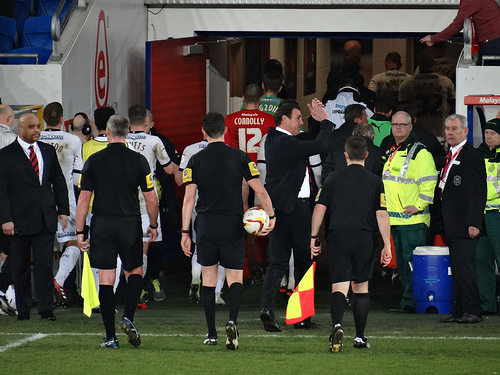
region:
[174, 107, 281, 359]
A man holding a soccer ball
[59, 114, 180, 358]
A referee holding a yellow flag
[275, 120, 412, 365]
A referee holding a checkered flag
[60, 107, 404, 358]
Three referees walking into a tunnel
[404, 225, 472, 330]
A blue water cooler on a field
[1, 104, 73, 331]
A man in a blue suit looking at something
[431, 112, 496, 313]
A man in a suit looking at something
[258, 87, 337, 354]
A man clapping his hands in the air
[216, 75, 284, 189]
A player in a red jersey walking into a tunnel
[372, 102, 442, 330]
A man in a yellow jacket looking at something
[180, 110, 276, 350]
Man wearing uniform holding red and white ball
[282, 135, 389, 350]
Man in uniform holding flag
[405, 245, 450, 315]
Blue and white water cooler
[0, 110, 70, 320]
Man in black tuxedo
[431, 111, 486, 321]
Man standing and watching players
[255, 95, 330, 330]
Man walking and making motion with hands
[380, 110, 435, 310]
Man wearing yellow and gray shirt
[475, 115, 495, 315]
Man wearing a black knit toboggan hat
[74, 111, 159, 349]
Man wearing uniform holding yellow towel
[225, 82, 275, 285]
Man wearing a red jersey with white letters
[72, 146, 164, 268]
man wearing black and yellow soccer uniform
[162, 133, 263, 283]
man wearing black and yellow soccer uniform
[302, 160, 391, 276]
man wearing black and yellow soccer uniform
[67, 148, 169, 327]
young man wearing black and yellow soccer uniform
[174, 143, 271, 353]
young man wearing black and yellow soccer uniform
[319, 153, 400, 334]
young man wearing black and yellow soccer uniform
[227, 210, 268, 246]
red and white ball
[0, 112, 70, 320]
He is wearing a suit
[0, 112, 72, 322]
His tie is striped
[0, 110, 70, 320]
his shirt is white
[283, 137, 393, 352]
he is carrying a flag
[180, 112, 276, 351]
he is carrying a ball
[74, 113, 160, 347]
he is carrying a flag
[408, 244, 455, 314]
the cooler is blue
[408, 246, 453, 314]
the lid is white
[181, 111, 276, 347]
his shorts are black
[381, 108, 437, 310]
his jacket is yellow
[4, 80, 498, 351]
a crowd in a game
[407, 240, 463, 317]
a blue water jug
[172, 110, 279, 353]
a guy carrying a soccer ball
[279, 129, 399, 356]
a boy carrying a flag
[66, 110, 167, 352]
a guy carrying a yellow piece of cloth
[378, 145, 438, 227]
a reflective top the guy is wearing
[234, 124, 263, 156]
a number 12 on the guy's uniform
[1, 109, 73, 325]
a bald guy wearing a suit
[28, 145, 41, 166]
a red and black tie the guy is wearing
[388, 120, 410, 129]
a sunglasses the guy is wearing